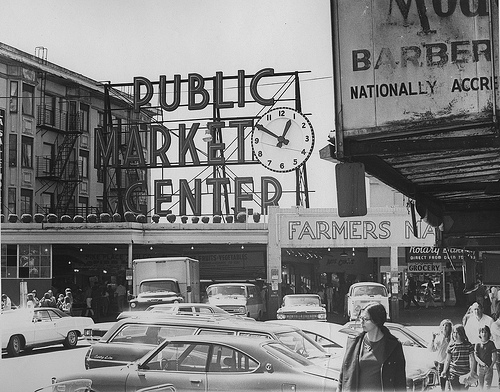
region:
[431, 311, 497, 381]
a group of children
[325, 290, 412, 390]
this is a woman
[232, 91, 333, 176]
this is a clock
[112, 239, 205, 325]
this is a truck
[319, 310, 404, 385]
woman wearing a jacket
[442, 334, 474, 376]
girl wearing a striped shirt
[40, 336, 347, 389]
this is a car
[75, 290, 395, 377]
this is a station wagon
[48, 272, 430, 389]
cars parked on the side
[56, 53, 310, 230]
large public market center sign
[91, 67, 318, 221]
Large sign above market roof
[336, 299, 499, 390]
People leaving after visiting market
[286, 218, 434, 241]
Sign for market close to larger sign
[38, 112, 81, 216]
Ladders attached to fire escapes on building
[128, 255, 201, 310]
Truck parked in front of the market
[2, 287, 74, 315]
Group of people standing in front of market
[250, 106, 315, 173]
White clock in front of large market sign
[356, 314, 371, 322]
Glasses on woman's face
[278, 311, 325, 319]
Headlights on front of car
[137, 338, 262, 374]
Windows on side of the car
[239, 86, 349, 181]
a clock on a sign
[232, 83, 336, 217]
a large clock on a sign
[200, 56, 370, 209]
an outside clock on a sign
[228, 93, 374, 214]
a large outside clock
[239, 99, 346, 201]
a clock that is outside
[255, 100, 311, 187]
a clcok that is large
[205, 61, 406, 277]
a sign with a clock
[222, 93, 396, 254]
a large otuside clock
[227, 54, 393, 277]
a sign with a large clock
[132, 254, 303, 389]
vehicles on the road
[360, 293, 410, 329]
head of a person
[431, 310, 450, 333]
head of a person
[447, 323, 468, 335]
head of a person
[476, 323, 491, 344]
head of a person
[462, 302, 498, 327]
head of a person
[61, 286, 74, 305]
head of a person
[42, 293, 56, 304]
head of a person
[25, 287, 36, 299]
head of a person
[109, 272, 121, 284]
head of a person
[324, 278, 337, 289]
head of a person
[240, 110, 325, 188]
white clock on sign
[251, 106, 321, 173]
black hands on clock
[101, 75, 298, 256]
large sign with clock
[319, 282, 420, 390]
woman walking near car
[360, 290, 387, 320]
woman has dark hair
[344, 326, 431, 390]
woman has dark coat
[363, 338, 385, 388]
woman has dark shirt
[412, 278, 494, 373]
group of children walking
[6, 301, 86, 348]
white car is parked